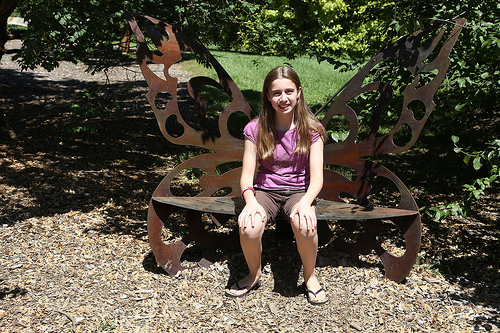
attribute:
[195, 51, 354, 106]
grass — green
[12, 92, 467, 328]
leaves — dried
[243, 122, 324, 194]
tee shirt — purple, cotton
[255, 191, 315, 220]
shorts — brown, cotton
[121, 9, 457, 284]
park bench — butterfly shaped, brown, metal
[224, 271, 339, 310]
flip flops — black, rubber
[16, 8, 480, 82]
leaves — green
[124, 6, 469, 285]
bench — butterfly-shaped, metal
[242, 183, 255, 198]
bracelet — pink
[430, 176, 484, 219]
leaves — green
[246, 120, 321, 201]
blouse — pink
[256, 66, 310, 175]
hair — long, blonde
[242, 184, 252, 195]
bracelet — pink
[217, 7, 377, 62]
leaves — green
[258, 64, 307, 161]
hair — long, brown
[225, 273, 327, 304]
flip flops — black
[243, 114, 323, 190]
shirt — purple, pink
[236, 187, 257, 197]
bracelet — Pink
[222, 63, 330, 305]
girl — young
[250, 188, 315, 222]
shorts — brown